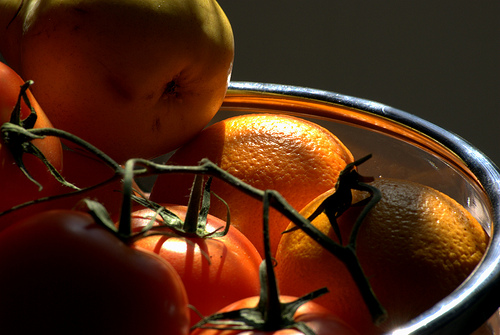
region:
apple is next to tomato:
[25, 0, 233, 169]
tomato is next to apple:
[0, 56, 66, 221]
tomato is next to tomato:
[1, 60, 64, 225]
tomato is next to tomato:
[4, 210, 187, 333]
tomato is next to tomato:
[108, 204, 267, 333]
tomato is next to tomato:
[192, 294, 349, 333]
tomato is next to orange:
[192, 296, 346, 334]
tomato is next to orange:
[111, 202, 266, 334]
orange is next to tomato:
[146, 112, 357, 263]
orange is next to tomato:
[271, 177, 488, 334]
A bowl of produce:
[7, 1, 492, 325]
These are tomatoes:
[6, 158, 316, 333]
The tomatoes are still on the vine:
[11, 133, 356, 322]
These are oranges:
[183, 115, 459, 308]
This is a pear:
[17, 4, 254, 141]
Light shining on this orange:
[228, 93, 322, 156]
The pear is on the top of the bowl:
[13, 2, 278, 137]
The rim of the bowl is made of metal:
[308, 70, 458, 155]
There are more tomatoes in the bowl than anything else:
[7, 31, 494, 324]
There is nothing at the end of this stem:
[356, 281, 402, 332]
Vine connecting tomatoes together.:
[2, 78, 384, 333]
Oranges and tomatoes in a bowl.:
[4, 0, 497, 334]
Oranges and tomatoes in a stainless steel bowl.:
[1, 0, 498, 333]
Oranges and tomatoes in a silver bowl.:
[1, 0, 498, 334]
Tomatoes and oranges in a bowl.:
[1, 0, 498, 333]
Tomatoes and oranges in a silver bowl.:
[1, 0, 498, 333]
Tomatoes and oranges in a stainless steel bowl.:
[1, 3, 498, 333]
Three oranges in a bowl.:
[2, 0, 499, 334]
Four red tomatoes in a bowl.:
[1, 0, 498, 333]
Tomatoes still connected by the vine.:
[1, 61, 386, 333]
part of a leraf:
[260, 289, 275, 319]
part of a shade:
[230, 258, 266, 291]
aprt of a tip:
[252, 290, 269, 324]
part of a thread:
[343, 157, 388, 217]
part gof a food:
[384, 159, 411, 206]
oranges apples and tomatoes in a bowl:
[0, 0, 495, 330]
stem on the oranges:
[10, 95, 400, 325]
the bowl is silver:
[220, 60, 490, 320]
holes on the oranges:
[370, 172, 470, 287]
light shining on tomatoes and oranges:
[136, 116, 477, 331]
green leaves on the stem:
[136, 191, 241, 256]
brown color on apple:
[77, 75, 173, 150]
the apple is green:
[15, 5, 295, 150]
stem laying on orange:
[303, 158, 404, 276]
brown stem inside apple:
[153, 74, 200, 106]